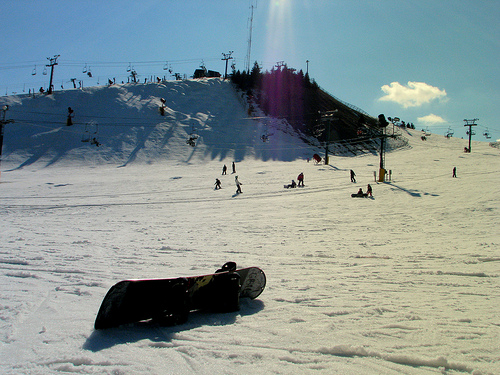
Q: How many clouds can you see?
A: Two.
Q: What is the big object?
A: Snowboard.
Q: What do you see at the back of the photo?
A: Ski lift.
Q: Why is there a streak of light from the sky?
A: It is sunny.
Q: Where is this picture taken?
A: Ski resort.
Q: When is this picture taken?
A: Winter.